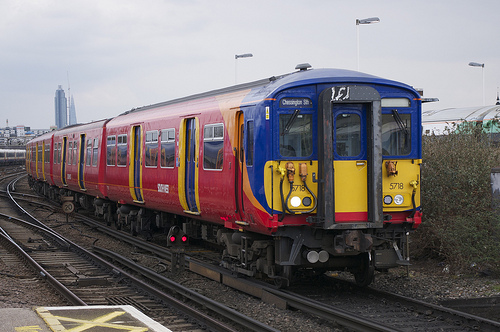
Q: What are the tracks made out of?
A: Metal.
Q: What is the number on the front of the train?
A: 5718.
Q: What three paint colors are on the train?
A: Red, blue and yellow.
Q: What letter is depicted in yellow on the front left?
A: X.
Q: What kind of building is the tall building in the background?
A: Skyscraper.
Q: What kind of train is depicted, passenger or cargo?
A: Passenger.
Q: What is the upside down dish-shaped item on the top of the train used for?
A: Exhaust.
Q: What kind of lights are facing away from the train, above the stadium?
A: Street lights.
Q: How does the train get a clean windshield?
A: Windshield wipers.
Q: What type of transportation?
A: Train.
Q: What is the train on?
A: Tracks.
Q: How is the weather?
A: Overcast.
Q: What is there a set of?
A: Tracks.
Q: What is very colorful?
A: The train.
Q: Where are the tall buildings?
A: In the background.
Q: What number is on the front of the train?
A: 5718.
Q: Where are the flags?
A: On the pole.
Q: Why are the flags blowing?
A: It is windy.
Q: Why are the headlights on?
A: To see.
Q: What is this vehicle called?
A: Train.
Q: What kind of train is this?
A: Passenger.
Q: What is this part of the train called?
A: Caboose.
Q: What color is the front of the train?
A: Yellow and blue.